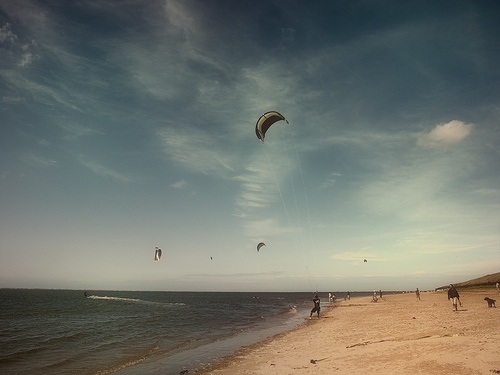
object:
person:
[347, 291, 350, 300]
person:
[380, 290, 384, 301]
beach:
[408, 305, 495, 372]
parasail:
[254, 108, 289, 144]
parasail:
[256, 242, 266, 253]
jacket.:
[448, 287, 460, 298]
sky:
[2, 0, 184, 26]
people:
[415, 288, 420, 302]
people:
[370, 290, 378, 303]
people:
[447, 284, 459, 313]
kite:
[257, 242, 267, 252]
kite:
[363, 259, 367, 263]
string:
[258, 123, 320, 295]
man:
[84, 291, 90, 298]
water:
[85, 288, 326, 319]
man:
[309, 291, 320, 319]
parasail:
[154, 246, 163, 263]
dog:
[484, 297, 497, 308]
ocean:
[49, 267, 184, 327]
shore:
[236, 280, 497, 372]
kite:
[153, 247, 162, 262]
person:
[344, 296, 346, 300]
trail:
[88, 295, 187, 307]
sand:
[353, 290, 412, 311]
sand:
[303, 331, 413, 359]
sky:
[18, 101, 145, 231]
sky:
[114, 225, 198, 275]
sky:
[349, 247, 386, 273]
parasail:
[359, 257, 375, 268]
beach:
[245, 312, 358, 375]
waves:
[84, 289, 190, 307]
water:
[19, 300, 39, 315]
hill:
[436, 268, 498, 291]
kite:
[254, 110, 289, 144]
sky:
[356, 65, 493, 208]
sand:
[442, 358, 500, 374]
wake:
[80, 287, 135, 305]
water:
[0, 343, 30, 375]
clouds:
[22, 21, 478, 237]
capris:
[450, 297, 457, 305]